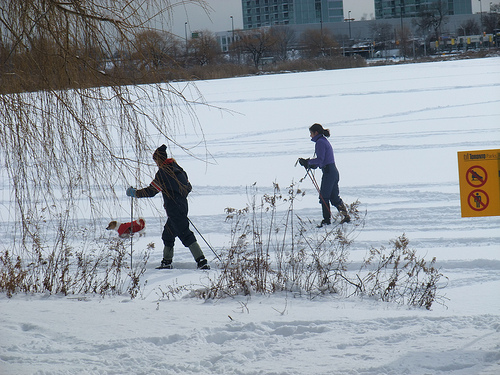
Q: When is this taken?
A: During the day.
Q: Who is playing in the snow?
A: The two kids.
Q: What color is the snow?
A: White.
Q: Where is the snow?
A: On the ground.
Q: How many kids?
A: Two.